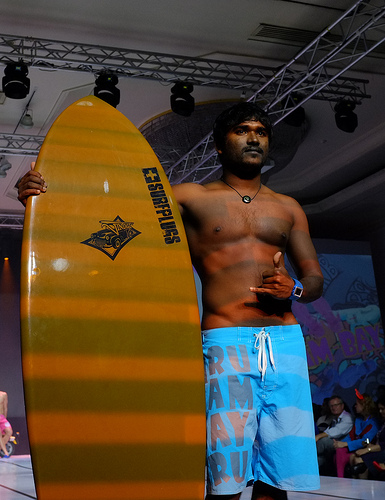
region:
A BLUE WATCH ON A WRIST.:
[288, 270, 304, 315]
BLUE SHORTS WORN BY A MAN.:
[203, 327, 318, 493]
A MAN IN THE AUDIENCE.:
[319, 398, 347, 449]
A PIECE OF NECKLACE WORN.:
[219, 172, 277, 210]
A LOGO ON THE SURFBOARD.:
[81, 215, 149, 287]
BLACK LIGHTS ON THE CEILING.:
[168, 84, 202, 116]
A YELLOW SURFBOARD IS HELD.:
[22, 94, 209, 499]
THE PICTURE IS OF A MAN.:
[213, 100, 279, 178]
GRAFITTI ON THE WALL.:
[308, 308, 384, 379]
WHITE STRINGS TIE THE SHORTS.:
[254, 330, 279, 380]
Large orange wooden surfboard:
[18, 76, 213, 499]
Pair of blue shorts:
[187, 313, 325, 498]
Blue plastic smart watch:
[283, 274, 308, 305]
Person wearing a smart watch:
[141, 85, 334, 499]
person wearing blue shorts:
[136, 91, 334, 499]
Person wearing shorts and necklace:
[121, 77, 339, 498]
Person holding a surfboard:
[10, 75, 347, 497]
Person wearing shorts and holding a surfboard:
[14, 76, 342, 490]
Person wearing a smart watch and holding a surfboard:
[18, 88, 370, 499]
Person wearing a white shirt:
[299, 392, 360, 467]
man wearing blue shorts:
[16, 104, 364, 491]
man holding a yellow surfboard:
[18, 101, 328, 494]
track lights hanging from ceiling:
[0, 0, 383, 194]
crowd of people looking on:
[311, 386, 383, 489]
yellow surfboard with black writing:
[14, 95, 211, 499]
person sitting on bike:
[0, 388, 20, 459]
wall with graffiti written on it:
[189, 252, 384, 393]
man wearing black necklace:
[17, 103, 333, 494]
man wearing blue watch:
[18, 99, 329, 496]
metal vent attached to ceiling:
[247, 21, 382, 58]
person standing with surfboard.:
[11, 77, 353, 467]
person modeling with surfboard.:
[12, 70, 337, 480]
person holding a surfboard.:
[11, 79, 341, 464]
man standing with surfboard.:
[1, 97, 321, 471]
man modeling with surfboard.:
[1, 68, 347, 485]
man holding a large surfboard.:
[11, 53, 346, 488]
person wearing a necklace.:
[218, 171, 270, 210]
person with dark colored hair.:
[200, 95, 281, 187]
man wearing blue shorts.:
[163, 96, 347, 493]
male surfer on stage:
[1, 1, 383, 499]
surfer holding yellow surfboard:
[13, 94, 323, 498]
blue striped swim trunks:
[200, 325, 320, 490]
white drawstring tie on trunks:
[250, 327, 275, 382]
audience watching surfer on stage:
[312, 395, 384, 481]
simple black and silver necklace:
[216, 175, 263, 204]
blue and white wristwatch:
[290, 276, 304, 301]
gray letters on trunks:
[206, 342, 254, 487]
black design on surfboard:
[78, 214, 141, 259]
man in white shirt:
[315, 398, 352, 468]